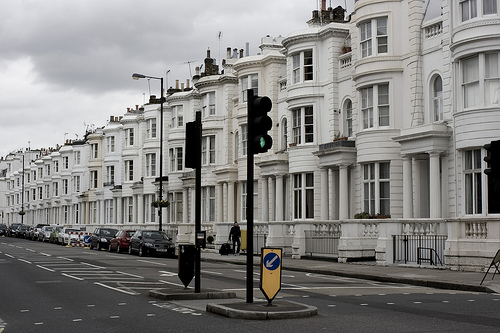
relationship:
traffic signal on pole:
[234, 89, 279, 311] [242, 161, 256, 311]